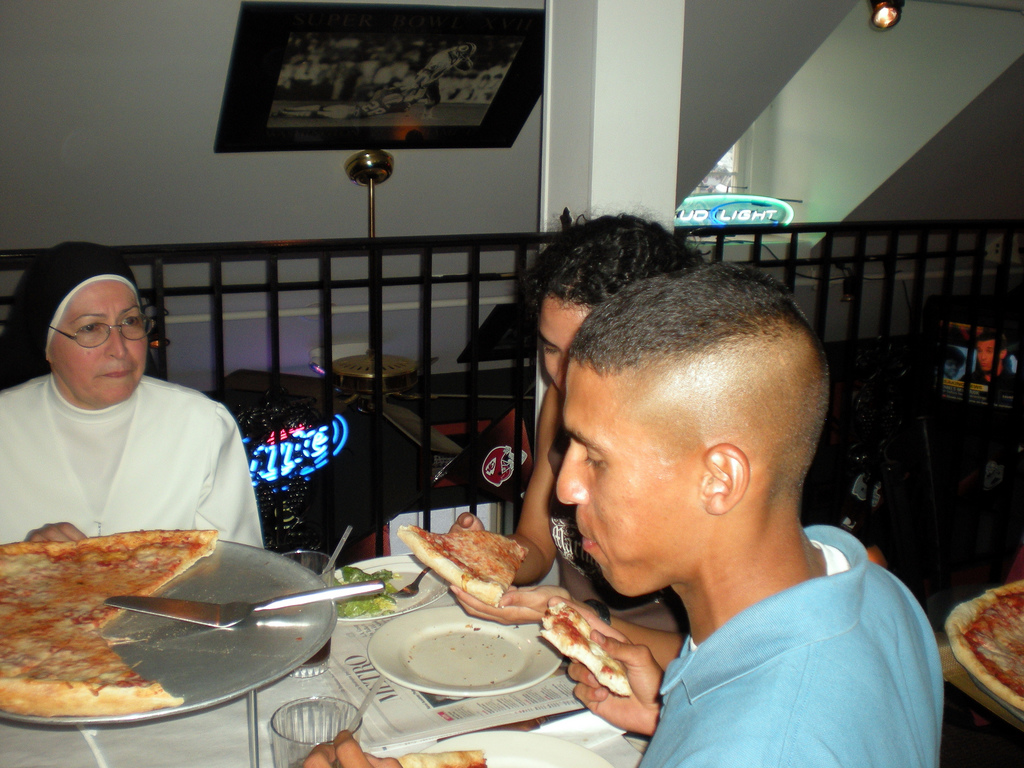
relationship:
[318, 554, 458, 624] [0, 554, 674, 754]
plates on table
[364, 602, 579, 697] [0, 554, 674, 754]
plates on table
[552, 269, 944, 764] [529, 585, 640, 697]
man holding pizza